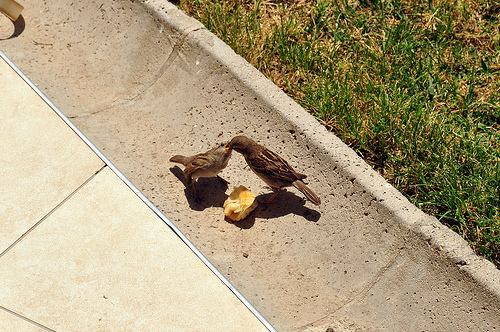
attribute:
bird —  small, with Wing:
[209, 125, 346, 200]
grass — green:
[357, 3, 495, 148]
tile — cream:
[0, 59, 251, 330]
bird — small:
[221, 130, 319, 211]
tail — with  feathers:
[294, 179, 321, 208]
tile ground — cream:
[1, 60, 271, 330]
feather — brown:
[260, 145, 279, 160]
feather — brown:
[246, 155, 271, 169]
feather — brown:
[295, 178, 325, 201]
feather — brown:
[287, 167, 309, 179]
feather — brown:
[264, 144, 289, 164]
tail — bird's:
[291, 179, 321, 207]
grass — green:
[456, 6, 498, 233]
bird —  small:
[226, 134, 322, 212]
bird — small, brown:
[230, 135, 321, 208]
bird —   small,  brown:
[228, 135, 320, 202]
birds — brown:
[170, 133, 327, 233]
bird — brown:
[222, 131, 327, 212]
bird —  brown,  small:
[174, 137, 339, 217]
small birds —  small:
[141, 121, 340, 228]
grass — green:
[181, 3, 499, 255]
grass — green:
[175, 2, 499, 232]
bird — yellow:
[221, 185, 258, 222]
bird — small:
[167, 137, 236, 184]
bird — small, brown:
[170, 143, 232, 185]